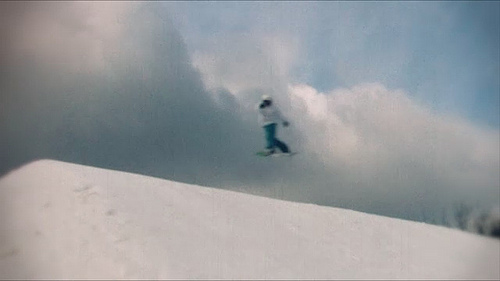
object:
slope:
[0, 158, 500, 281]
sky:
[1, 0, 500, 233]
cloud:
[0, 0, 499, 238]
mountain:
[1, 157, 498, 280]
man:
[256, 89, 295, 156]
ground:
[0, 157, 499, 280]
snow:
[0, 158, 500, 281]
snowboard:
[252, 149, 298, 161]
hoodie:
[257, 102, 287, 127]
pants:
[261, 123, 293, 153]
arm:
[255, 101, 265, 117]